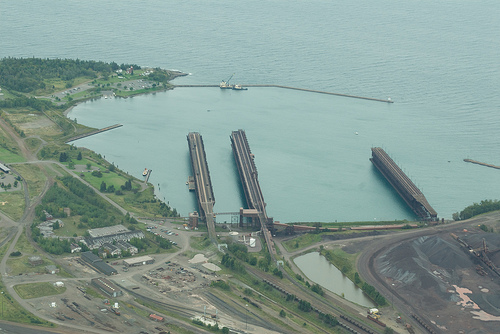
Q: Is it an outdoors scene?
A: Yes, it is outdoors.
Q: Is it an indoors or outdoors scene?
A: It is outdoors.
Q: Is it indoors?
A: No, it is outdoors.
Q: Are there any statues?
A: No, there are no statues.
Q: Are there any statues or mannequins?
A: No, there are no statues or mannequins.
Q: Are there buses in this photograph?
A: No, there are no buses.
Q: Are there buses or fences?
A: No, there are no buses or fences.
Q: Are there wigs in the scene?
A: No, there are no wigs.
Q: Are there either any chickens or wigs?
A: No, there are no wigs or chickens.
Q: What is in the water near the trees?
A: The barrier is in the water.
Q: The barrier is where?
A: The barrier is in the water.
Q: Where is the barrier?
A: The barrier is in the water.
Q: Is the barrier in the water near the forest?
A: Yes, the barrier is in the water.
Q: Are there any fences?
A: No, there are no fences.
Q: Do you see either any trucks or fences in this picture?
A: No, there are no fences or trucks.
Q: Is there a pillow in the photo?
A: No, there are no pillows.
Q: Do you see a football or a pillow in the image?
A: No, there are no pillows or footballs.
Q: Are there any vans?
A: No, there are no vans.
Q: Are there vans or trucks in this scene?
A: No, there are no vans or trucks.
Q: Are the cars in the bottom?
A: Yes, the cars are in the bottom of the image.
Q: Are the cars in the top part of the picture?
A: No, the cars are in the bottom of the image.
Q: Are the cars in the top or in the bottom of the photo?
A: The cars are in the bottom of the image.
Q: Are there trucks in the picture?
A: No, there are no trucks.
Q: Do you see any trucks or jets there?
A: No, there are no trucks or jets.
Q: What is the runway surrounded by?
A: The runway is surrounded by the water.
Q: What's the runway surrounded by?
A: The runway is surrounded by the water.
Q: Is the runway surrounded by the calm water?
A: Yes, the runway is surrounded by the water.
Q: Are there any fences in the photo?
A: No, there are no fences.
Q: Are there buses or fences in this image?
A: No, there are no fences or buses.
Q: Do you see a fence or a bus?
A: No, there are no fences or buses.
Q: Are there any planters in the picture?
A: No, there are no planters.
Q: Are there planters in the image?
A: No, there are no planters.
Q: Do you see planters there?
A: No, there are no planters.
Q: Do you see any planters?
A: No, there are no planters.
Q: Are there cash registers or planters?
A: No, there are no planters or cash registers.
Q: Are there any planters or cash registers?
A: No, there are no planters or cash registers.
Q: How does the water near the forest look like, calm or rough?
A: The water is calm.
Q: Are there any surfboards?
A: No, there are no surfboards.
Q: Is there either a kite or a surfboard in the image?
A: No, there are no surfboards or kites.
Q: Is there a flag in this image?
A: No, there are no flags.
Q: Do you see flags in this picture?
A: No, there are no flags.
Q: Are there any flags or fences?
A: No, there are no flags or fences.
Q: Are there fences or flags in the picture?
A: No, there are no flags or fences.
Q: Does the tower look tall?
A: Yes, the tower is tall.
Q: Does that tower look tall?
A: Yes, the tower is tall.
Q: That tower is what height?
A: The tower is tall.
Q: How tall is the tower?
A: The tower is tall.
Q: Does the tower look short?
A: No, the tower is tall.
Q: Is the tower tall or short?
A: The tower is tall.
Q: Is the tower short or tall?
A: The tower is tall.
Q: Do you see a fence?
A: No, there are no fences.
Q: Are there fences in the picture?
A: No, there are no fences.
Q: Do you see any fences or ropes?
A: No, there are no fences or ropes.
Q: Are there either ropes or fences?
A: No, there are no fences or ropes.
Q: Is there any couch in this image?
A: No, there are no couches.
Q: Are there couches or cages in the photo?
A: No, there are no couches or cages.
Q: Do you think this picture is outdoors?
A: Yes, the picture is outdoors.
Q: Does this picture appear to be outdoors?
A: Yes, the picture is outdoors.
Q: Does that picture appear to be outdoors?
A: Yes, the picture is outdoors.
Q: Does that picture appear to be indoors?
A: No, the picture is outdoors.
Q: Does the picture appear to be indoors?
A: No, the picture is outdoors.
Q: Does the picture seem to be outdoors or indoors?
A: The picture is outdoors.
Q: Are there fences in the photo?
A: No, there are no fences.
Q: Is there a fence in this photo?
A: No, there are no fences.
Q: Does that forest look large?
A: Yes, the forest is large.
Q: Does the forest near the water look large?
A: Yes, the forest is large.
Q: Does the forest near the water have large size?
A: Yes, the forest is large.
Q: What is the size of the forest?
A: The forest is large.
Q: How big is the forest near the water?
A: The forest is large.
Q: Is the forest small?
A: No, the forest is large.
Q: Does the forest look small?
A: No, the forest is large.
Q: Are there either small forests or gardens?
A: No, there is a forest but it is large.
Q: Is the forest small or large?
A: The forest is large.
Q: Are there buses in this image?
A: No, there are no buses.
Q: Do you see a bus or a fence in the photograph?
A: No, there are no buses or fences.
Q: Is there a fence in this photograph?
A: No, there are no fences.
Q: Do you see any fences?
A: No, there are no fences.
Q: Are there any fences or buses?
A: No, there are no fences or buses.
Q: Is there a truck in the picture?
A: No, there are no trucks.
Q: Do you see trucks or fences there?
A: No, there are no trucks or fences.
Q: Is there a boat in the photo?
A: Yes, there is a boat.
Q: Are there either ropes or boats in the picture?
A: Yes, there is a boat.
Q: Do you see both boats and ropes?
A: No, there is a boat but no ropes.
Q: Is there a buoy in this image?
A: No, there are no buoys.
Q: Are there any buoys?
A: No, there are no buoys.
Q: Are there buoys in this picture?
A: No, there are no buoys.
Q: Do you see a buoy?
A: No, there are no buoys.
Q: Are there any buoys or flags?
A: No, there are no buoys or flags.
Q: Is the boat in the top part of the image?
A: Yes, the boat is in the top of the image.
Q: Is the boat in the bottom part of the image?
A: No, the boat is in the top of the image.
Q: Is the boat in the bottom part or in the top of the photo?
A: The boat is in the top of the image.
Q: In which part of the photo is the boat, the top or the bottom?
A: The boat is in the top of the image.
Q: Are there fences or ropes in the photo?
A: No, there are no fences or ropes.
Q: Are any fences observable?
A: No, there are no fences.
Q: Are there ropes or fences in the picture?
A: No, there are no fences or ropes.